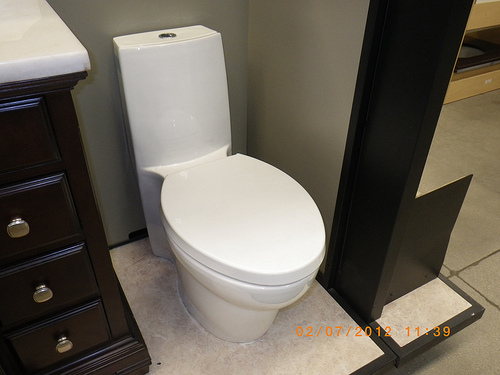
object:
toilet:
[112, 24, 327, 343]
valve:
[158, 32, 177, 39]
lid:
[160, 153, 327, 286]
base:
[142, 144, 327, 342]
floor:
[107, 235, 384, 374]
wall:
[49, 0, 370, 277]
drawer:
[0, 172, 83, 266]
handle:
[8, 217, 30, 238]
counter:
[1, 1, 92, 85]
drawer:
[0, 242, 100, 332]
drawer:
[3, 298, 114, 375]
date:
[296, 326, 451, 338]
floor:
[373, 88, 500, 375]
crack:
[441, 247, 500, 311]